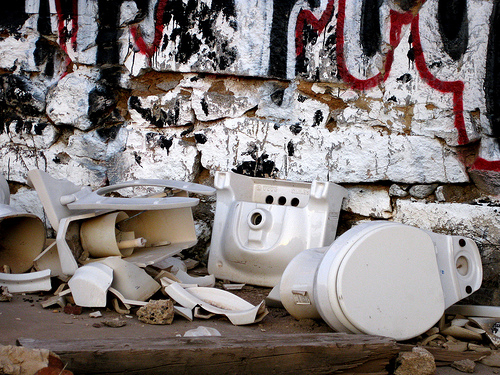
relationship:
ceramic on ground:
[0, 170, 484, 340] [2, 285, 497, 372]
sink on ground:
[207, 169, 349, 288] [2, 285, 497, 372]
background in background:
[1, 0, 499, 273] [1, 0, 499, 273]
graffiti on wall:
[0, 1, 495, 186] [0, 1, 498, 226]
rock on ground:
[136, 298, 174, 324] [1, 273, 499, 371]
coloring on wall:
[404, 10, 429, 67] [0, 2, 498, 189]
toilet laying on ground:
[33, 159, 223, 329] [1, 273, 499, 371]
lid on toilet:
[336, 224, 446, 341] [276, 216, 486, 342]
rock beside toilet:
[136, 296, 172, 326] [266, 221, 484, 338]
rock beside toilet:
[392, 342, 432, 372] [266, 221, 484, 338]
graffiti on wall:
[0, 0, 500, 186] [0, 0, 496, 318]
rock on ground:
[91, 316, 128, 328] [40, 302, 253, 368]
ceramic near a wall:
[0, 170, 484, 340] [0, 0, 496, 318]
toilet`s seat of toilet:
[326, 221, 445, 342] [266, 221, 484, 338]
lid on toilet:
[337, 223, 446, 337] [266, 221, 484, 338]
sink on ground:
[206, 170, 348, 291] [0, 287, 366, 337]